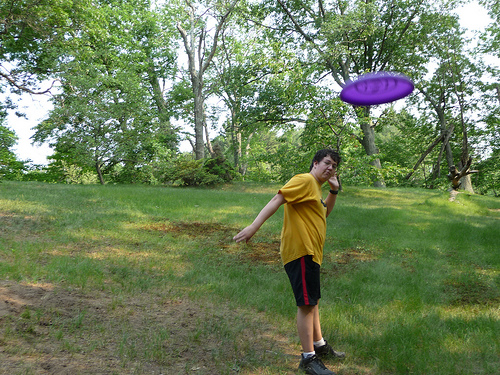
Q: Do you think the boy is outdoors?
A: Yes, the boy is outdoors.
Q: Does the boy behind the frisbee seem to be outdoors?
A: Yes, the boy is outdoors.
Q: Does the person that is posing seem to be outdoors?
A: Yes, the boy is outdoors.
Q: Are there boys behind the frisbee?
A: Yes, there is a boy behind the frisbee.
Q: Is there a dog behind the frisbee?
A: No, there is a boy behind the frisbee.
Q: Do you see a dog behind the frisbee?
A: No, there is a boy behind the frisbee.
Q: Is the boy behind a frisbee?
A: Yes, the boy is behind a frisbee.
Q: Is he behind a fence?
A: No, the boy is behind a frisbee.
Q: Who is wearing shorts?
A: The boy is wearing shorts.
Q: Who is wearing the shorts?
A: The boy is wearing shorts.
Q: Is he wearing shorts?
A: Yes, the boy is wearing shorts.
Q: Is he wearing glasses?
A: No, the boy is wearing shorts.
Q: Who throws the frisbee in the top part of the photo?
A: The boy throws the frisbee.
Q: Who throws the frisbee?
A: The boy throws the frisbee.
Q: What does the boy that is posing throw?
A: The boy throws the frisbee.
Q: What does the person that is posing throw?
A: The boy throws the frisbee.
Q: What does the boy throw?
A: The boy throws the frisbee.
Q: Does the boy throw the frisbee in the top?
A: Yes, the boy throws the frisbee.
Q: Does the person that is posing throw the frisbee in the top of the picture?
A: Yes, the boy throws the frisbee.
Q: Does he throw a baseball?
A: No, the boy throws the frisbee.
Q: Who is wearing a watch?
A: The boy is wearing a watch.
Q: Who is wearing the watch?
A: The boy is wearing a watch.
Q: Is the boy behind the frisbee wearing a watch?
A: Yes, the boy is wearing a watch.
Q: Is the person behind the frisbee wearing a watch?
A: Yes, the boy is wearing a watch.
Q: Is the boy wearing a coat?
A: No, the boy is wearing a watch.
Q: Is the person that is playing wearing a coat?
A: No, the boy is wearing a watch.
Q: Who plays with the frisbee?
A: The boy plays with the frisbee.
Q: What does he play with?
A: The boy plays with a frisbee.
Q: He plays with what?
A: The boy plays with a frisbee.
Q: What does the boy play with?
A: The boy plays with a frisbee.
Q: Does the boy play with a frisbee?
A: Yes, the boy plays with a frisbee.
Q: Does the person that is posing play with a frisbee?
A: Yes, the boy plays with a frisbee.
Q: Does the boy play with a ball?
A: No, the boy plays with a frisbee.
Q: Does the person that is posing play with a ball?
A: No, the boy plays with a frisbee.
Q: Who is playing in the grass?
A: The boy is playing in the grass.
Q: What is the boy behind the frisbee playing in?
A: The boy is playing in the grass.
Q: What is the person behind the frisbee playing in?
A: The boy is playing in the grass.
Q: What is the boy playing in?
A: The boy is playing in the grass.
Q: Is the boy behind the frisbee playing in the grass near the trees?
A: Yes, the boy is playing in the grass.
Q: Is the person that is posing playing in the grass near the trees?
A: Yes, the boy is playing in the grass.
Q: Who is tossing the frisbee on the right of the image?
A: The boy is tossing the frisbee.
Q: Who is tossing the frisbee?
A: The boy is tossing the frisbee.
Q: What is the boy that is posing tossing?
A: The boy is tossing the frisbee.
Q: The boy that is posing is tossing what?
A: The boy is tossing the frisbee.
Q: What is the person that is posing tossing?
A: The boy is tossing the frisbee.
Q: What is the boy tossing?
A: The boy is tossing the frisbee.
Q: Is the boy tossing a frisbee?
A: Yes, the boy is tossing a frisbee.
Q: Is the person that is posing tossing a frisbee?
A: Yes, the boy is tossing a frisbee.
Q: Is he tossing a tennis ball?
A: No, the boy is tossing a frisbee.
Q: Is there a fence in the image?
A: No, there are no fences.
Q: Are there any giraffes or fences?
A: No, there are no fences or giraffes.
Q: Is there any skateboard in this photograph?
A: No, there are no skateboards.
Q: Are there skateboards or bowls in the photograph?
A: No, there are no skateboards or bowls.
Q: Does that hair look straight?
A: Yes, the hair is straight.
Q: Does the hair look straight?
A: Yes, the hair is straight.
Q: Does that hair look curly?
A: No, the hair is straight.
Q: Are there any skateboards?
A: No, there are no skateboards.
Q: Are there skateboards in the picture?
A: No, there are no skateboards.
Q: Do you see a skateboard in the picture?
A: No, there are no skateboards.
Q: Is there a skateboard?
A: No, there are no skateboards.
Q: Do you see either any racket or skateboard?
A: No, there are no skateboards or rackets.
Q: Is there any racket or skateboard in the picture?
A: No, there are no skateboards or rackets.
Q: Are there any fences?
A: No, there are no fences.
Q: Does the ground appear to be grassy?
A: Yes, the ground is grassy.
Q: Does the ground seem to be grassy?
A: Yes, the ground is grassy.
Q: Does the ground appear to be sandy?
A: No, the ground is grassy.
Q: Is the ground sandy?
A: No, the ground is grassy.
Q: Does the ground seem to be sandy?
A: No, the ground is grassy.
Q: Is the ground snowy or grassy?
A: The ground is grassy.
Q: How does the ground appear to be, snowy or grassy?
A: The ground is grassy.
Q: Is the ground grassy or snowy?
A: The ground is grassy.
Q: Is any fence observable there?
A: No, there are no fences.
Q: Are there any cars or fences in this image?
A: No, there are no fences or cars.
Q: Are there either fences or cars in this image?
A: No, there are no fences or cars.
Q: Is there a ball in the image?
A: No, there are no balls.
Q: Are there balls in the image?
A: No, there are no balls.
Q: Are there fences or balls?
A: No, there are no balls or fences.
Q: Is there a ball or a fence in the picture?
A: No, there are no balls or fences.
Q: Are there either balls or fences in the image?
A: No, there are no balls or fences.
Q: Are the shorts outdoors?
A: Yes, the shorts are outdoors.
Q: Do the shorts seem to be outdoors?
A: Yes, the shorts are outdoors.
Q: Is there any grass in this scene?
A: Yes, there is grass.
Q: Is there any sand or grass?
A: Yes, there is grass.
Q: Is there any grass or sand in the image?
A: Yes, there is grass.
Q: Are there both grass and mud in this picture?
A: No, there is grass but no mud.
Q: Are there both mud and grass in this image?
A: No, there is grass but no mud.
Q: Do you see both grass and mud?
A: No, there is grass but no mud.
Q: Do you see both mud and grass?
A: No, there is grass but no mud.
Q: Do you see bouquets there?
A: No, there are no bouquets.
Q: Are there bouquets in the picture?
A: No, there are no bouquets.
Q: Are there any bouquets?
A: No, there are no bouquets.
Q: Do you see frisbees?
A: Yes, there is a frisbee.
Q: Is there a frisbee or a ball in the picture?
A: Yes, there is a frisbee.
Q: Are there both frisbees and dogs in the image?
A: No, there is a frisbee but no dogs.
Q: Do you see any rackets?
A: No, there are no rackets.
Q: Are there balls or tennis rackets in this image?
A: No, there are no tennis rackets or balls.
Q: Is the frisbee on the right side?
A: Yes, the frisbee is on the right of the image.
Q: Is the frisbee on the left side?
A: No, the frisbee is on the right of the image.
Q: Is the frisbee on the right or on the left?
A: The frisbee is on the right of the image.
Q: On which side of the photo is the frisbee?
A: The frisbee is on the right of the image.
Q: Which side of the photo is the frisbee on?
A: The frisbee is on the right of the image.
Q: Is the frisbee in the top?
A: Yes, the frisbee is in the top of the image.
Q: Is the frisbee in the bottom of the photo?
A: No, the frisbee is in the top of the image.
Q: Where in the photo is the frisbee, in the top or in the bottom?
A: The frisbee is in the top of the image.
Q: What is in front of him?
A: The frisbee is in front of the boy.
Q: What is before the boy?
A: The frisbee is in front of the boy.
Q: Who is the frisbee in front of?
A: The frisbee is in front of the boy.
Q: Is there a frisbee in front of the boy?
A: Yes, there is a frisbee in front of the boy.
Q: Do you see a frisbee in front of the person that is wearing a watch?
A: Yes, there is a frisbee in front of the boy.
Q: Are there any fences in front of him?
A: No, there is a frisbee in front of the boy.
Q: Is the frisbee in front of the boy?
A: Yes, the frisbee is in front of the boy.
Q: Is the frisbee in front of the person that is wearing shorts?
A: Yes, the frisbee is in front of the boy.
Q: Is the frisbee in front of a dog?
A: No, the frisbee is in front of the boy.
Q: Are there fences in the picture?
A: No, there are no fences.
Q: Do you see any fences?
A: No, there are no fences.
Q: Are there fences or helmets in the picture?
A: No, there are no fences or helmets.